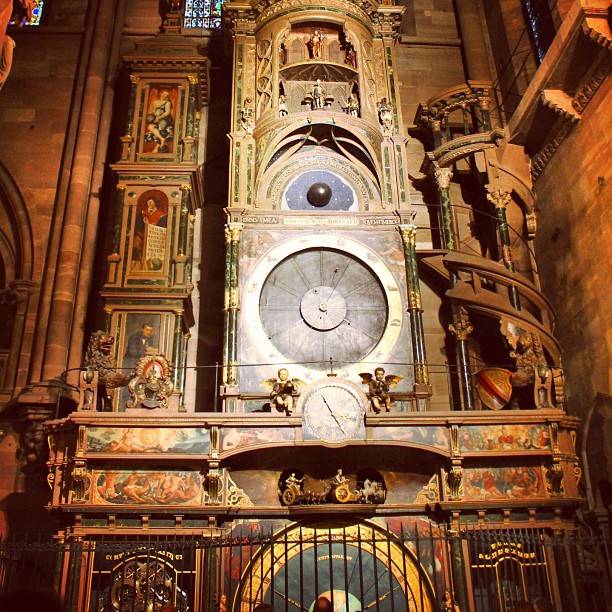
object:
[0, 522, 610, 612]
railing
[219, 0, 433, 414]
tower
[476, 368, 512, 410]
sash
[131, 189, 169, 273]
painting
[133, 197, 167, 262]
man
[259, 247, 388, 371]
face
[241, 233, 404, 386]
clock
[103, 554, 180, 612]
machine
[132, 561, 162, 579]
gear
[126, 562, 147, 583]
gear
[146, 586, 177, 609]
gear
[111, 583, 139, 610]
gear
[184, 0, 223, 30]
window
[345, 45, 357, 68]
figurine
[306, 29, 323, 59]
figurine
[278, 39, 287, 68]
figurine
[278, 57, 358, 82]
shelf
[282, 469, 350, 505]
decoration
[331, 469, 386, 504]
decoration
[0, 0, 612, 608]
wall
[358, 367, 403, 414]
decoration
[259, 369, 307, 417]
decoration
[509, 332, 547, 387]
decoration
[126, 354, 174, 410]
decoration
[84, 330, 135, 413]
decoration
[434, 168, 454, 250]
decoration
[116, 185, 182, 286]
decoration